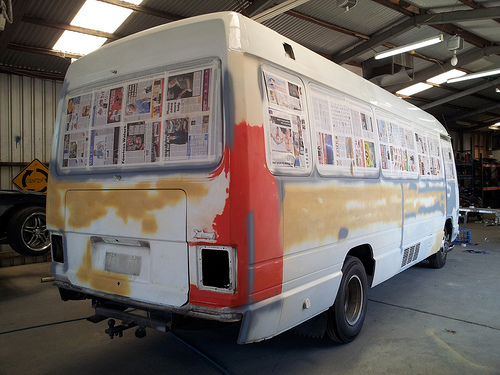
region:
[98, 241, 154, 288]
license plate on back of van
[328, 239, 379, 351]
rear tire and wheel on van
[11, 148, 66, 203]
yellow and black street sign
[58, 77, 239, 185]
newspaper print covering back window of van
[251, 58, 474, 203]
newspaper print covering side windows on van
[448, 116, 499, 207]
shelves inside garage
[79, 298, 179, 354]
towing hitch on back of van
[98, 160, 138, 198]
keyed lock on back of van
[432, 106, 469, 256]
front side door of van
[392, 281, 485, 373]
cement on floor inside garage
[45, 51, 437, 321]
Van is under the shed.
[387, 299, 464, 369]
Road is grey color.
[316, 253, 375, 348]
Tyre is black color.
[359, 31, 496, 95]
Light is in the roof.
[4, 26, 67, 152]
Shed is grey color.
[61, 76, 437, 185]
News paper is stick to the mirror.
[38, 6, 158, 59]
Sun light is passing through the glass.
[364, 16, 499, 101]
Lights are on.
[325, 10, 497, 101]
rods are brown color.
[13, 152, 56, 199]
Board is yellow and black color.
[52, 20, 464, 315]
The van is parked in the garage.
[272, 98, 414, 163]
The van has newspaper on the windows.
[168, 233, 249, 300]
The bumper lights are missing.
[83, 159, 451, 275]
The van has fainted paint.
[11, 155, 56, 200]
A yellow sign posted to the wall.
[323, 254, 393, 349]
The van has black tire.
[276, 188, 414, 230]
The van has yellow and red painting.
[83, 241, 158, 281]
The license plate is missing from the van.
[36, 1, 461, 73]
The lights are on the ceiling.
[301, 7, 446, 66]
The building is made of aluminum.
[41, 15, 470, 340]
Van prepared for painting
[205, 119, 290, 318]
Repairs need to the body of a van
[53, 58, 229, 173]
Newspapers attached to the rear window of a van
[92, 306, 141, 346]
Trailer hitch attached to van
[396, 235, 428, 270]
Air vents in side of a van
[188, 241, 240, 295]
Hole for taillights of the van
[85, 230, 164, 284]
Area for license plate on a van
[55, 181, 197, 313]
Access door on back of a van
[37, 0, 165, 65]
Skylights built into the roof of the garage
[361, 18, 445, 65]
Overhead lighting in a garage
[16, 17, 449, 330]
van covered with newspaper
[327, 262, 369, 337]
wheel on side of van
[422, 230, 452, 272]
wheel on side of van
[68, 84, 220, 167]
back window of van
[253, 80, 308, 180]
side window of van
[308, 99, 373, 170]
side window of van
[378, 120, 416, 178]
side window of van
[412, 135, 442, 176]
side window of van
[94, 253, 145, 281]
back license plate holder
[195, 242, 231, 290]
tail light spot on van